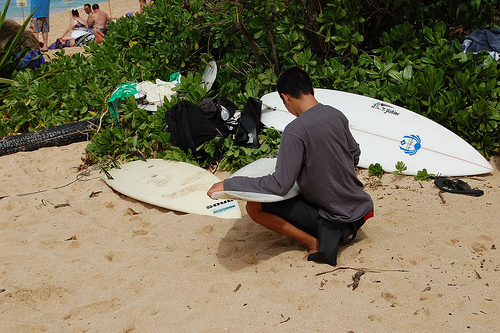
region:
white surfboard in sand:
[82, 128, 246, 239]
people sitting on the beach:
[9, 2, 125, 62]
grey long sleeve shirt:
[215, 105, 376, 236]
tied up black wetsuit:
[243, 197, 388, 279]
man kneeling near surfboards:
[183, 56, 498, 286]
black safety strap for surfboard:
[422, 163, 488, 212]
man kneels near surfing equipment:
[56, 42, 498, 287]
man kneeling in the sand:
[5, 4, 499, 324]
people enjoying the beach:
[1, 0, 127, 324]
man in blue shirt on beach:
[18, 3, 56, 61]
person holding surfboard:
[203, 82, 378, 305]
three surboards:
[63, 106, 483, 280]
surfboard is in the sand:
[68, 150, 276, 269]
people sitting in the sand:
[35, 7, 147, 81]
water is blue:
[50, 4, 116, 25]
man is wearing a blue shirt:
[25, 0, 72, 24]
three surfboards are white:
[89, 94, 497, 228]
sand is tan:
[36, 229, 211, 331]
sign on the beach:
[11, 1, 41, 25]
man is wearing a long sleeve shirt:
[200, 110, 405, 246]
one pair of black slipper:
[431, 157, 493, 211]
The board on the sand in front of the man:
[95, 153, 244, 225]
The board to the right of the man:
[251, 78, 499, 190]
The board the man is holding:
[209, 148, 302, 208]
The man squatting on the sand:
[208, 58, 383, 266]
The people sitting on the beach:
[51, 0, 152, 60]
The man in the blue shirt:
[26, 1, 55, 51]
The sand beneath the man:
[1, 144, 498, 331]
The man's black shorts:
[266, 199, 379, 267]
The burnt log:
[0, 113, 105, 163]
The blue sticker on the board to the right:
[391, 127, 425, 159]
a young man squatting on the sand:
[204, 66, 376, 266]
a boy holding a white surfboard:
[206, 65, 377, 265]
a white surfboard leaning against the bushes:
[260, 88, 492, 178]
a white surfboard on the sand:
[103, 159, 241, 219]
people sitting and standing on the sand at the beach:
[2, 0, 154, 51]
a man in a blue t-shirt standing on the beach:
[30, 0, 52, 47]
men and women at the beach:
[2, 0, 495, 268]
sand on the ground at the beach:
[0, 229, 211, 329]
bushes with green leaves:
[157, 0, 437, 58]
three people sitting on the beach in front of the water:
[55, 2, 111, 48]